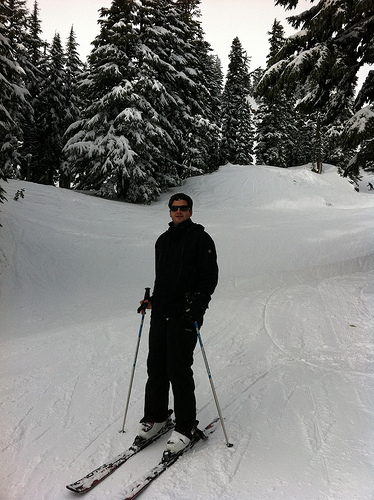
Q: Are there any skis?
A: Yes, there are skis.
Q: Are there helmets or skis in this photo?
A: Yes, there are skis.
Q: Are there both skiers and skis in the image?
A: Yes, there are both skis and a skier.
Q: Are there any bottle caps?
A: No, there are no bottle caps.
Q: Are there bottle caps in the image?
A: No, there are no bottle caps.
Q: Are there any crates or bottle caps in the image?
A: No, there are no bottle caps or crates.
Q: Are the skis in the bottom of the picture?
A: Yes, the skis are in the bottom of the image.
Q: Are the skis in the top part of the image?
A: No, the skis are in the bottom of the image.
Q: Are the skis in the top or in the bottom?
A: The skis are in the bottom of the image.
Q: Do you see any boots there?
A: Yes, there are boots.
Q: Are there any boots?
A: Yes, there are boots.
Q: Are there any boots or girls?
A: Yes, there are boots.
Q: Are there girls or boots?
A: Yes, there are boots.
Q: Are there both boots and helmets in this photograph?
A: No, there are boots but no helmets.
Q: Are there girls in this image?
A: No, there are no girls.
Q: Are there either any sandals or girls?
A: No, there are no girls or sandals.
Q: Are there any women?
A: No, there are no women.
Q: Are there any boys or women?
A: No, there are no women or boys.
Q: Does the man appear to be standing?
A: Yes, the man is standing.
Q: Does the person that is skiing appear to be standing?
A: Yes, the man is standing.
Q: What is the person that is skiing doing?
A: The man is standing.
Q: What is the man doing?
A: The man is standing.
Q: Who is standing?
A: The man is standing.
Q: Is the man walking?
A: No, the man is standing.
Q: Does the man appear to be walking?
A: No, the man is standing.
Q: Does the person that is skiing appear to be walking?
A: No, the man is standing.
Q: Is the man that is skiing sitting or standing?
A: The man is standing.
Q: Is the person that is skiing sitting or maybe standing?
A: The man is standing.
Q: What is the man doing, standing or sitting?
A: The man is standing.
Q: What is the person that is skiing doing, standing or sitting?
A: The man is standing.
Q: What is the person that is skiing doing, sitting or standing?
A: The man is standing.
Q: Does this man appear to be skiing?
A: Yes, the man is skiing.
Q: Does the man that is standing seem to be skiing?
A: Yes, the man is skiing.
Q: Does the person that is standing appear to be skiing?
A: Yes, the man is skiing.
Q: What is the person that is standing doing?
A: The man is skiing.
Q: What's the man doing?
A: The man is skiing.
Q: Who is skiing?
A: The man is skiing.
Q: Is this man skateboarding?
A: No, the man is skiing.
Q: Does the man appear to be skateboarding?
A: No, the man is skiing.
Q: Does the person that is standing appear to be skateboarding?
A: No, the man is skiing.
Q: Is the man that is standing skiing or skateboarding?
A: The man is skiing.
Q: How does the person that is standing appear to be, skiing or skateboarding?
A: The man is skiing.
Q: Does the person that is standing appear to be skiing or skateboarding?
A: The man is skiing.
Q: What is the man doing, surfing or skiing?
A: The man is skiing.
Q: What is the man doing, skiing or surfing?
A: The man is skiing.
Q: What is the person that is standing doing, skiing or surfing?
A: The man is skiing.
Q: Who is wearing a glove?
A: The man is wearing a glove.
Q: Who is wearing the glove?
A: The man is wearing a glove.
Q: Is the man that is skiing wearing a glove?
A: Yes, the man is wearing a glove.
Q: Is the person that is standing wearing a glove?
A: Yes, the man is wearing a glove.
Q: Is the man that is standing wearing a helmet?
A: No, the man is wearing a glove.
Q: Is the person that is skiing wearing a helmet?
A: No, the man is wearing a glove.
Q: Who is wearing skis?
A: The man is wearing skis.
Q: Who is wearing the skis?
A: The man is wearing skis.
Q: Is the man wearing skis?
A: Yes, the man is wearing skis.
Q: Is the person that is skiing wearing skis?
A: Yes, the man is wearing skis.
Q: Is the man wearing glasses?
A: No, the man is wearing skis.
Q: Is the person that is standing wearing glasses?
A: No, the man is wearing skis.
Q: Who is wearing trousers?
A: The man is wearing trousers.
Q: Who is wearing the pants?
A: The man is wearing trousers.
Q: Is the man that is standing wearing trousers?
A: Yes, the man is wearing trousers.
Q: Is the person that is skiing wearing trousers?
A: Yes, the man is wearing trousers.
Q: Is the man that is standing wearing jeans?
A: No, the man is wearing trousers.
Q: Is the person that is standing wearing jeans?
A: No, the man is wearing trousers.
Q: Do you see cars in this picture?
A: No, there are no cars.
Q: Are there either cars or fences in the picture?
A: No, there are no cars or fences.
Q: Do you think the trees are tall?
A: Yes, the trees are tall.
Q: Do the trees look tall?
A: Yes, the trees are tall.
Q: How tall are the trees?
A: The trees are tall.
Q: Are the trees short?
A: No, the trees are tall.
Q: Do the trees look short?
A: No, the trees are tall.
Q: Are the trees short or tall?
A: The trees are tall.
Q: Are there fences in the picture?
A: No, there are no fences.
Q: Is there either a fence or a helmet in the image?
A: No, there are no fences or helmets.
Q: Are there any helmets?
A: No, there are no helmets.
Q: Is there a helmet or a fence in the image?
A: No, there are no helmets or fences.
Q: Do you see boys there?
A: No, there are no boys.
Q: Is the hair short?
A: Yes, the hair is short.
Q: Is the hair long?
A: No, the hair is short.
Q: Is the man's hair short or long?
A: The hair is short.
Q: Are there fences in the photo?
A: No, there are no fences.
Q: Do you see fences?
A: No, there are no fences.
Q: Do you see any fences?
A: No, there are no fences.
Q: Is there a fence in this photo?
A: No, there are no fences.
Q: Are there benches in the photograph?
A: No, there are no benches.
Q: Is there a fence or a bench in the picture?
A: No, there are no benches or fences.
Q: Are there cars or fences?
A: No, there are no fences or cars.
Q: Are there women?
A: No, there are no women.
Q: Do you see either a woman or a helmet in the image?
A: No, there are no women or helmets.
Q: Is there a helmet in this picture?
A: No, there are no helmets.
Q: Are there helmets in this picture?
A: No, there are no helmets.